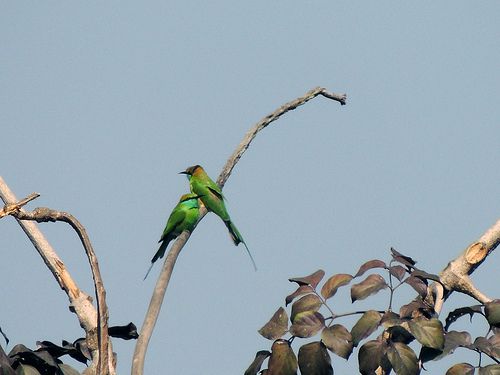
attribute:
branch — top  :
[132, 85, 347, 372]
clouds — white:
[51, 33, 244, 181]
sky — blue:
[328, 51, 469, 164]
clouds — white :
[392, 31, 459, 112]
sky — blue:
[350, 47, 490, 98]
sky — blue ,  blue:
[0, 15, 493, 370]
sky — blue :
[1, 1, 498, 140]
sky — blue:
[15, 7, 474, 219]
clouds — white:
[49, 72, 140, 117]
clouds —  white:
[190, 290, 283, 347]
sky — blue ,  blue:
[9, 9, 472, 334]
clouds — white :
[331, 155, 498, 239]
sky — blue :
[340, 47, 496, 85]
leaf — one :
[319, 267, 359, 299]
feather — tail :
[225, 220, 265, 283]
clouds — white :
[89, 30, 140, 72]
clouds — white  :
[38, 21, 289, 123]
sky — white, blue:
[62, 18, 317, 87]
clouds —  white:
[402, 87, 454, 123]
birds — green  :
[149, 160, 244, 267]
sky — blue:
[1, 0, 496, 209]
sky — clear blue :
[363, 7, 482, 212]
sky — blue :
[379, 127, 474, 198]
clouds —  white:
[380, 34, 417, 75]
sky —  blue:
[16, 3, 492, 160]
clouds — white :
[191, 78, 331, 164]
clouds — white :
[256, 190, 329, 262]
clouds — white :
[245, 179, 325, 251]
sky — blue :
[9, 10, 465, 250]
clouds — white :
[238, 210, 320, 262]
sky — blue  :
[3, 15, 467, 207]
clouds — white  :
[269, 190, 334, 246]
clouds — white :
[259, 198, 332, 259]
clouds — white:
[8, 4, 244, 133]